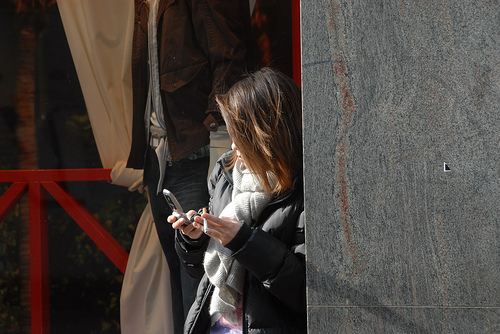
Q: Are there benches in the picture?
A: No, there are no benches.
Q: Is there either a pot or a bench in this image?
A: No, there are no benches or pots.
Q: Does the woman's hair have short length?
A: Yes, the hair is short.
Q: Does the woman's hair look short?
A: Yes, the hair is short.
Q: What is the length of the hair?
A: The hair is short.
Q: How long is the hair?
A: The hair is short.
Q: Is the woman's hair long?
A: No, the hair is short.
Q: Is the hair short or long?
A: The hair is short.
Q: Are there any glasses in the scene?
A: No, there are no glasses.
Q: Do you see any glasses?
A: No, there are no glasses.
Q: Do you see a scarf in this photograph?
A: Yes, there is a scarf.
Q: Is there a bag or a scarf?
A: Yes, there is a scarf.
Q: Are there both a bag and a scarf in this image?
A: No, there is a scarf but no bags.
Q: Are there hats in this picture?
A: No, there are no hats.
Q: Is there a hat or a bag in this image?
A: No, there are no hats or bags.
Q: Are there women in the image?
A: Yes, there is a woman.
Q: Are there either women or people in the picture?
A: Yes, there is a woman.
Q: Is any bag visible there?
A: No, there are no bags.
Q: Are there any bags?
A: No, there are no bags.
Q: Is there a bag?
A: No, there are no bags.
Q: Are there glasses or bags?
A: No, there are no bags or glasses.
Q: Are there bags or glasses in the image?
A: No, there are no bags or glasses.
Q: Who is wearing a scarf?
A: The woman is wearing a scarf.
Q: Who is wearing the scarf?
A: The woman is wearing a scarf.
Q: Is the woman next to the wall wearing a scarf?
A: Yes, the woman is wearing a scarf.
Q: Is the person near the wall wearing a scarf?
A: Yes, the woman is wearing a scarf.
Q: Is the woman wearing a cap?
A: No, the woman is wearing a scarf.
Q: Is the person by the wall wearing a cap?
A: No, the woman is wearing a scarf.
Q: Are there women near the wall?
A: Yes, there is a woman near the wall.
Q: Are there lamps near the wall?
A: No, there is a woman near the wall.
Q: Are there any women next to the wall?
A: Yes, there is a woman next to the wall.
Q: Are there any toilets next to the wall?
A: No, there is a woman next to the wall.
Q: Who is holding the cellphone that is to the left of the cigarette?
A: The woman is holding the cell phone.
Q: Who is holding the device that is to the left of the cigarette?
A: The woman is holding the cell phone.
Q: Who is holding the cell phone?
A: The woman is holding the cell phone.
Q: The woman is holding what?
A: The woman is holding the mobile phone.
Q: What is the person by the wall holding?
A: The woman is holding the mobile phone.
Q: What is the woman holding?
A: The woman is holding the mobile phone.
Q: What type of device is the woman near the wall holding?
A: The woman is holding the cellphone.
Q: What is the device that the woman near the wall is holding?
A: The device is a cell phone.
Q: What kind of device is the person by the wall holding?
A: The woman is holding the cellphone.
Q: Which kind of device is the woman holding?
A: The woman is holding the cellphone.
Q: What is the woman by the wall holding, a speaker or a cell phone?
A: The woman is holding a cell phone.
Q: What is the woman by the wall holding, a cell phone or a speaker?
A: The woman is holding a cell phone.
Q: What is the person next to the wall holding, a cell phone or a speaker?
A: The woman is holding a cell phone.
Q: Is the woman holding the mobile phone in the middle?
A: Yes, the woman is holding the mobile phone.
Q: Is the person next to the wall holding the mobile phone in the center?
A: Yes, the woman is holding the mobile phone.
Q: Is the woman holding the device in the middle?
A: Yes, the woman is holding the mobile phone.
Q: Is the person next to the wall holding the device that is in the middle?
A: Yes, the woman is holding the mobile phone.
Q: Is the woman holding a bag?
A: No, the woman is holding the mobile phone.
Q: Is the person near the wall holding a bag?
A: No, the woman is holding the mobile phone.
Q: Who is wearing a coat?
A: The woman is wearing a coat.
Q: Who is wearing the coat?
A: The woman is wearing a coat.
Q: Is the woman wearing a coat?
A: Yes, the woman is wearing a coat.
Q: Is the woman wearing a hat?
A: No, the woman is wearing a coat.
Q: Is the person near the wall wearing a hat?
A: No, the woman is wearing a coat.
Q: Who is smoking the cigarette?
A: The woman is smoking the cigarette.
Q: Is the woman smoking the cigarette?
A: Yes, the woman is smoking the cigarette.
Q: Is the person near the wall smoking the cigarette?
A: Yes, the woman is smoking the cigarette.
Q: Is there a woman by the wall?
A: Yes, there is a woman by the wall.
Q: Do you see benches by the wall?
A: No, there is a woman by the wall.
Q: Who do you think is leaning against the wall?
A: The woman is leaning against the wall.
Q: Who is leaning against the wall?
A: The woman is leaning against the wall.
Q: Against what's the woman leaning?
A: The woman is leaning against the wall.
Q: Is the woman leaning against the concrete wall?
A: Yes, the woman is leaning against the wall.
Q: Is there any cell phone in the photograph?
A: Yes, there is a cell phone.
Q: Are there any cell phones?
A: Yes, there is a cell phone.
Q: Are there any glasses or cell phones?
A: Yes, there is a cell phone.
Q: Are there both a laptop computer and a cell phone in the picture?
A: No, there is a cell phone but no laptops.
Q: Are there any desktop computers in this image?
A: No, there are no desktop computers.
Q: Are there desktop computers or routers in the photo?
A: No, there are no desktop computers or routers.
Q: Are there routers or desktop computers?
A: No, there are no desktop computers or routers.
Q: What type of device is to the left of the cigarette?
A: The device is a cell phone.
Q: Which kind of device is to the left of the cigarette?
A: The device is a cell phone.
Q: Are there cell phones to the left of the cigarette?
A: Yes, there is a cell phone to the left of the cigarette.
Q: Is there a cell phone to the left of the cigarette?
A: Yes, there is a cell phone to the left of the cigarette.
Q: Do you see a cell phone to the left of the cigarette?
A: Yes, there is a cell phone to the left of the cigarette.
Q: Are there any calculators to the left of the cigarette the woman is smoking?
A: No, there is a cell phone to the left of the cigarette.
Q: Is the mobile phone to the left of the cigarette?
A: Yes, the mobile phone is to the left of the cigarette.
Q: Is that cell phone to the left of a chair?
A: No, the cell phone is to the left of the cigarette.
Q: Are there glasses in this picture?
A: No, there are no glasses.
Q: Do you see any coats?
A: Yes, there is a coat.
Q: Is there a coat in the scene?
A: Yes, there is a coat.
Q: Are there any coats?
A: Yes, there is a coat.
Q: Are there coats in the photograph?
A: Yes, there is a coat.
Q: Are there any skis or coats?
A: Yes, there is a coat.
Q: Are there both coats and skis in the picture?
A: No, there is a coat but no skis.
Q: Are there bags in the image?
A: No, there are no bags.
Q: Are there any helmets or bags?
A: No, there are no bags or helmets.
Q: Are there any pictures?
A: No, there are no pictures.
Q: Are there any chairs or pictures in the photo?
A: No, there are no pictures or chairs.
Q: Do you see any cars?
A: No, there are no cars.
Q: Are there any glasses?
A: No, there are no glasses.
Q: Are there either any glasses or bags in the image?
A: No, there are no glasses or bags.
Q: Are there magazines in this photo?
A: No, there are no magazines.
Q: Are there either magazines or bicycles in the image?
A: No, there are no magazines or bicycles.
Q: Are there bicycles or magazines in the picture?
A: No, there are no magazines or bicycles.